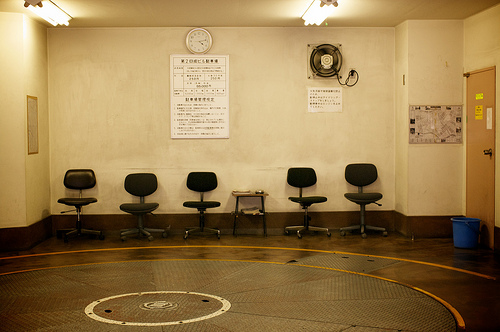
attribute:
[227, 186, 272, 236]
table — small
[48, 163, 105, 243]
office chair — black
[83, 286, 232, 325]
circle — white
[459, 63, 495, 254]
door — brown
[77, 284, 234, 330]
circle — White 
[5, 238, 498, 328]
floor — warehouse 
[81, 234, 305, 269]
lines — yellow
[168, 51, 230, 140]
poster — white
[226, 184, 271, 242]
table — small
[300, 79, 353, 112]
sign — white, black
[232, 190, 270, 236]
table — Small 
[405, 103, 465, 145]
safety poster — Safety floor plan 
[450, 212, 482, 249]
bucket — blue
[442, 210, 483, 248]
basket — blue   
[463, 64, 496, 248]
door — wood 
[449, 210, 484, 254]
bucket — blue round 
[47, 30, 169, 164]
wall — White 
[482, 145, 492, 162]
door handle — metal door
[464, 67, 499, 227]
door — wooden 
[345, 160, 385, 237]
office chair — office 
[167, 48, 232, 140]
sign — Asian language 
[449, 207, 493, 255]
bucket — blue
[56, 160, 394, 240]
office chairs — 5 black office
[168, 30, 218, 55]
clock — White 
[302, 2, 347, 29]
fixture — ceiling light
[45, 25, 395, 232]
wall — white 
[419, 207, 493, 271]
trashcan — Small blue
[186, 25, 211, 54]
clock — white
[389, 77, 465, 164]
wall — white 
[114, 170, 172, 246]
desk chair — black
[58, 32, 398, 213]
wall — White 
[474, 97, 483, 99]
sign — yellow  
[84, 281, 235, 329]
circle — white 